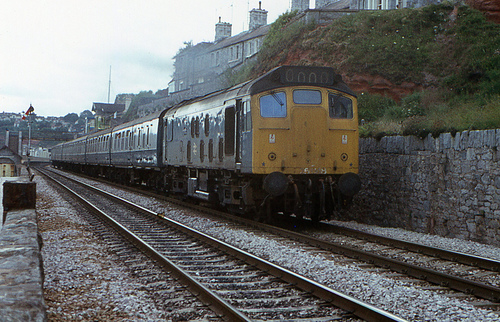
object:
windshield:
[261, 91, 290, 119]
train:
[51, 63, 362, 227]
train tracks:
[26, 161, 417, 322]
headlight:
[263, 150, 278, 164]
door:
[220, 105, 240, 159]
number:
[267, 132, 280, 145]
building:
[191, 0, 281, 88]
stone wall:
[336, 127, 500, 246]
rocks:
[46, 164, 500, 322]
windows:
[292, 89, 327, 107]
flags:
[24, 105, 37, 116]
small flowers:
[391, 40, 399, 45]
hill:
[270, 0, 500, 96]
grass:
[261, 0, 500, 132]